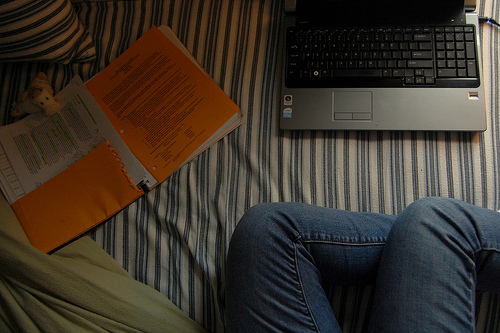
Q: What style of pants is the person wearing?
A: Jeans.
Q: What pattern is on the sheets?
A: Stripes.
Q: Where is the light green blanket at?
A: Bottom left corner.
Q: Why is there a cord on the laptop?
A: It is charging.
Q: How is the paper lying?
A: Face up.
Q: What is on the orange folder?
A: A stuffed animal.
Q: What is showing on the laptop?
A: The keyboard.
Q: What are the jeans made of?
A: Denim.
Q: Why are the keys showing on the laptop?
A: It is open.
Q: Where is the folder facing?
A: Up.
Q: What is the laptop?
A: Silver.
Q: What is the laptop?
A: Silver and black.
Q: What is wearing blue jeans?
A: The person.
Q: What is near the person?
A: Some booklets.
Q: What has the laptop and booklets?
A: The person.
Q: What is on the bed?
A: Striped sheet.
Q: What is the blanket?
A: Light green.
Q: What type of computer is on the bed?
A: Laptop.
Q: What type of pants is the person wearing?
A: Blue jeans.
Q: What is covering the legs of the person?
A: Blue jeans.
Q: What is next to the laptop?
A: Orange piece of paper.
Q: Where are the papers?
A: In an orange folder.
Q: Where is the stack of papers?
A: On the bed.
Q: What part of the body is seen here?
A: Legs.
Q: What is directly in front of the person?
A: Laptop.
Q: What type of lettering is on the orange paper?
A: Black lettering.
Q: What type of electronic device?
A: Laptop.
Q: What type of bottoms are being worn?
A: Jeans.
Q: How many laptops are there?
A: One.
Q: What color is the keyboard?
A: Black.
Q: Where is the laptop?
A: On the bed.